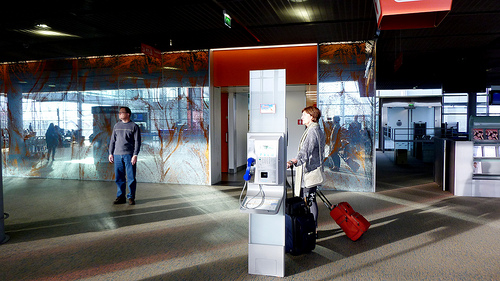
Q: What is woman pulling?
A: Suitcase.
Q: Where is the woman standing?
A: Next to phone booth.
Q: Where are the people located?
A: At an airport.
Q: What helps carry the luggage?
A: Handles.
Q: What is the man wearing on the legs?
A: Jeans.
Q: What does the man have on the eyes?
A: Eyeglasses.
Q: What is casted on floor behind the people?
A: Shadows.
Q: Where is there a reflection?
A: On the lobby wall.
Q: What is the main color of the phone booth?
A: White.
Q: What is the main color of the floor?
A: Gray.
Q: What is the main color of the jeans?
A: Blue.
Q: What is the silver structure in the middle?
A: Phone.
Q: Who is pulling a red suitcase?
A: Woman.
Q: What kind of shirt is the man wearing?
A: Sweater.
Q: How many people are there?
A: 2.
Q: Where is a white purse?
A: Woman's shoulder.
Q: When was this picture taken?
A: Daytime.